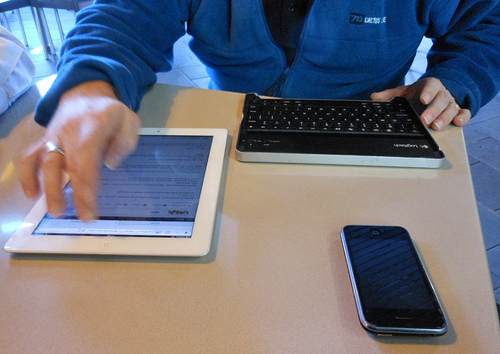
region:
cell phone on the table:
[336, 215, 448, 335]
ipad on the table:
[0, 125, 225, 260]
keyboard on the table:
[232, 85, 442, 175]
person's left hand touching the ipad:
[15, 77, 147, 217]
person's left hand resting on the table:
[365, 75, 465, 130]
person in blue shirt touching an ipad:
[30, 0, 490, 110]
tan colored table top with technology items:
[0, 70, 495, 345]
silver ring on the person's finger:
[40, 136, 61, 146]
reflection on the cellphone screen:
[352, 237, 431, 312]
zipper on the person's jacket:
[248, 0, 323, 97]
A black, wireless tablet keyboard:
[236, 92, 448, 168]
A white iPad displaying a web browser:
[3, 126, 228, 256]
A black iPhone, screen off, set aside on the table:
[339, 223, 449, 337]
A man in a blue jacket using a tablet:
[16, 1, 498, 221]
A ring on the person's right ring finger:
[37, 141, 67, 158]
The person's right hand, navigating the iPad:
[18, 82, 140, 224]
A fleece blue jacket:
[34, 0, 499, 127]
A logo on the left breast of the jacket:
[345, 11, 387, 26]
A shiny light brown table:
[0, 71, 498, 352]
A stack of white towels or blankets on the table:
[0, 23, 37, 115]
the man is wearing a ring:
[43, 138, 66, 159]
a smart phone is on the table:
[341, 223, 451, 338]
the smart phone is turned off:
[338, 223, 449, 343]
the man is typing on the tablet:
[18, 87, 132, 221]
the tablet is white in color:
[15, 125, 229, 260]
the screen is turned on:
[42, 133, 214, 235]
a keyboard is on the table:
[236, 91, 448, 169]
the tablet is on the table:
[6, 124, 228, 265]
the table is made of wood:
[1, 73, 496, 350]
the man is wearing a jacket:
[31, 0, 492, 118]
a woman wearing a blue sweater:
[33, 0, 497, 124]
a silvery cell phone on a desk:
[340, 222, 448, 335]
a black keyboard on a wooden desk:
[236, 91, 446, 168]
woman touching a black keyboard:
[238, 74, 474, 169]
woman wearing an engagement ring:
[41, 135, 65, 157]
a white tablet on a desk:
[5, 124, 230, 258]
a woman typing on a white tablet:
[7, 93, 227, 251]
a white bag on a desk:
[1, 28, 38, 115]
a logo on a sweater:
[348, 11, 389, 25]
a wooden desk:
[1, 68, 498, 352]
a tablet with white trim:
[4, 127, 228, 254]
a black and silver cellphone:
[344, 225, 449, 331]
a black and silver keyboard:
[237, 94, 446, 166]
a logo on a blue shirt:
[349, 13, 390, 25]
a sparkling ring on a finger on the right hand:
[40, 140, 65, 156]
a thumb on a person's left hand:
[370, 84, 408, 101]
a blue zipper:
[255, 1, 318, 96]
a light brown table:
[0, 82, 499, 351]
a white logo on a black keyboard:
[394, 142, 431, 149]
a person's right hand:
[17, 85, 139, 221]